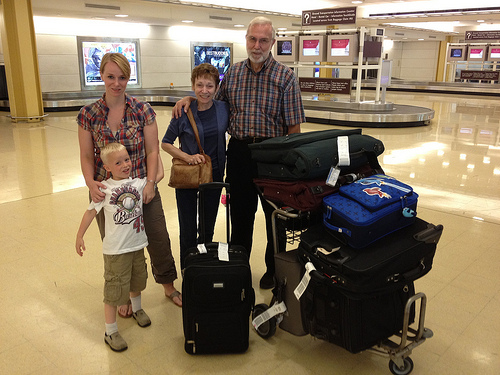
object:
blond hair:
[100, 51, 134, 81]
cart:
[252, 163, 442, 375]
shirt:
[86, 178, 151, 257]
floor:
[0, 87, 500, 375]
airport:
[0, 0, 500, 375]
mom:
[78, 53, 186, 313]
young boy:
[75, 140, 187, 354]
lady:
[161, 61, 235, 270]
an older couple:
[160, 17, 307, 285]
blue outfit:
[161, 100, 229, 179]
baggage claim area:
[0, 88, 436, 129]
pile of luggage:
[249, 126, 441, 375]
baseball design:
[103, 185, 154, 233]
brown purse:
[168, 99, 209, 188]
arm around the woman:
[167, 73, 225, 119]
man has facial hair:
[243, 43, 273, 66]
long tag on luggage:
[320, 135, 353, 192]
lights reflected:
[371, 134, 499, 186]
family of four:
[69, 17, 307, 351]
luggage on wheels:
[384, 356, 414, 375]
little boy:
[73, 141, 160, 350]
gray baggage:
[273, 249, 315, 337]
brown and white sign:
[293, 262, 316, 301]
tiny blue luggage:
[320, 173, 420, 248]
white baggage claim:
[334, 135, 352, 167]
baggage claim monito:
[327, 35, 358, 64]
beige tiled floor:
[0, 168, 499, 375]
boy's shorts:
[100, 243, 148, 307]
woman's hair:
[188, 61, 224, 88]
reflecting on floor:
[0, 91, 499, 219]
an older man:
[171, 15, 307, 294]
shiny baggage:
[74, 32, 144, 91]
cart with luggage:
[248, 128, 443, 375]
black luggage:
[176, 183, 257, 353]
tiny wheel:
[371, 136, 387, 161]